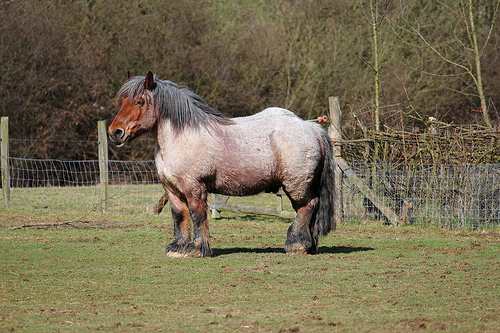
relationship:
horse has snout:
[110, 73, 354, 261] [99, 117, 133, 149]